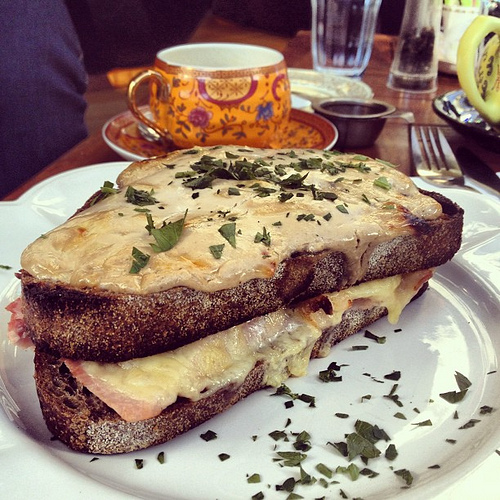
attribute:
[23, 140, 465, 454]
sandwich — large, green, browned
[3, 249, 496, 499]
plate — large, white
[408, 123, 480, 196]
fork — silver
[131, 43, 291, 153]
teacup — colorful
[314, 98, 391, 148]
container — small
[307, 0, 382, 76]
glass — empty, clear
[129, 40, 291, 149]
cup — orange, black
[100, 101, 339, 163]
saucer — orange